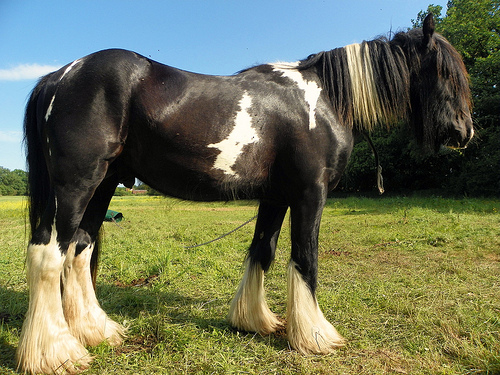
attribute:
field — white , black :
[1, 194, 498, 373]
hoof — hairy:
[276, 269, 319, 349]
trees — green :
[345, 4, 498, 194]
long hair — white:
[224, 250, 346, 358]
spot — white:
[203, 86, 268, 187]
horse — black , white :
[9, 23, 467, 340]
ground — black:
[390, 91, 455, 171]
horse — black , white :
[12, 19, 480, 367]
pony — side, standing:
[12, 28, 474, 373]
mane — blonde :
[301, 29, 420, 133]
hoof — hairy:
[4, 331, 98, 372]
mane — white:
[315, 35, 415, 132]